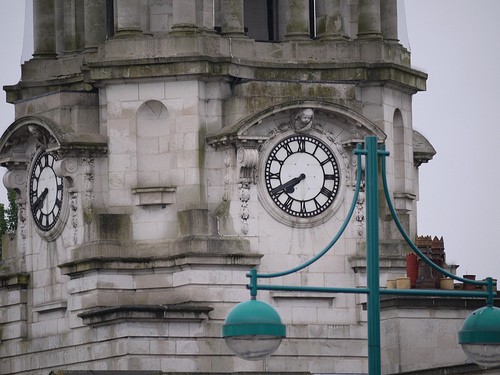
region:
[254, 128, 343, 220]
clock on front of building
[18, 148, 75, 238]
clock on side of building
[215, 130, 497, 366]
blue light structure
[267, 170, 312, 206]
big and little hand on front clock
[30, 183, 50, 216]
big and little hands on side clock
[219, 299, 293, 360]
light fixture on left side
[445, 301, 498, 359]
light fixture on right side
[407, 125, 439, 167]
overhang on right side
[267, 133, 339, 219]
roman numerals on front facing clock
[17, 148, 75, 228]
roman numerals on side facing clock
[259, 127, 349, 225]
round black and white clock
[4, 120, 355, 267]
two round white clocks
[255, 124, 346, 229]
round clock on side of building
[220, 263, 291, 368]
round blue street lamp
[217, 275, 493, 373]
two round street lamps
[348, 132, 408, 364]
tall metal blue post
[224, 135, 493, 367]
two lights attached to post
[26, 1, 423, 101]
dirty grey stone columns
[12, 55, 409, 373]
building made of stone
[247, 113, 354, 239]
round stone clock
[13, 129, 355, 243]
two clock faces on wall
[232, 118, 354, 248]
the clock face is white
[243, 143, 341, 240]
clock hands are black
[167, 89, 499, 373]
the lamp post is blue green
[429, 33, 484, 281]
the sky is cloudy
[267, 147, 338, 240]
the clock shows 8:40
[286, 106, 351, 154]
an angel stone sculpture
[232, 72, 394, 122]
moss on the wall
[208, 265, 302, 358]
the lamp is off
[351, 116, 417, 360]
the pole is made of steel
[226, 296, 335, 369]
a street light in front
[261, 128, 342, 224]
a clock in the buiding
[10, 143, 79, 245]
a clock on the other side of the building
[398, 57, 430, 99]
a stone inlay on the building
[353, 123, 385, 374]
a pole with lights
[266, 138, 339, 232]
the clock has a white face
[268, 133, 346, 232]
numbers on the clock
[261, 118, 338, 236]
the clock is showing the time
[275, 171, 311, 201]
hand of the clock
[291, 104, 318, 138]
a stone statue on the building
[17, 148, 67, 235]
Black and white clock face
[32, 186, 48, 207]
Clock minute and hour hands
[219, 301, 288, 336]
Green dome of light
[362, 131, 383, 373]
Long green lamp post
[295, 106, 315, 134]
Carved gray statue on wall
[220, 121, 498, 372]
Lamp post with two lights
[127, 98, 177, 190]
Arched indentation on wall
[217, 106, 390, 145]
Curved stone roof over clock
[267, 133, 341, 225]
Clock with roman numerals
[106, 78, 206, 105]
Three gray bricks in wall